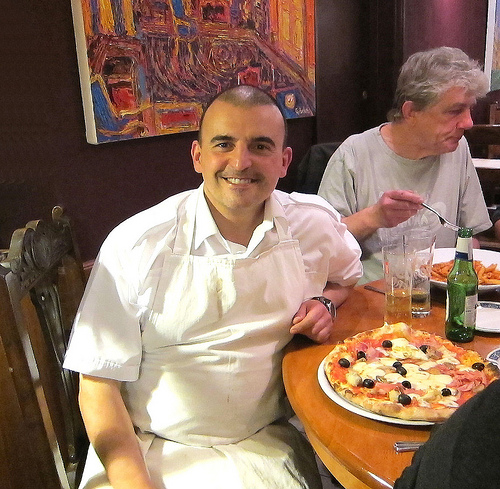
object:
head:
[200, 84, 286, 210]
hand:
[288, 297, 334, 343]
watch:
[310, 296, 338, 317]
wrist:
[313, 293, 336, 312]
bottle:
[445, 227, 478, 344]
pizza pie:
[388, 403, 419, 420]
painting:
[71, 0, 316, 145]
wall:
[315, 0, 394, 111]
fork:
[421, 202, 464, 234]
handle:
[392, 438, 427, 453]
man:
[62, 84, 364, 487]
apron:
[78, 187, 323, 487]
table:
[345, 426, 407, 480]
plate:
[430, 246, 499, 293]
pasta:
[419, 258, 499, 284]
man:
[315, 44, 494, 285]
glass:
[380, 242, 414, 329]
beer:
[383, 291, 413, 326]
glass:
[402, 227, 437, 320]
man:
[317, 44, 494, 271]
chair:
[5, 205, 86, 487]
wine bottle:
[443, 226, 479, 343]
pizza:
[324, 320, 498, 419]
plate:
[317, 351, 437, 425]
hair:
[387, 45, 489, 123]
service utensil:
[392, 439, 425, 452]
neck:
[207, 208, 263, 234]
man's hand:
[367, 189, 422, 228]